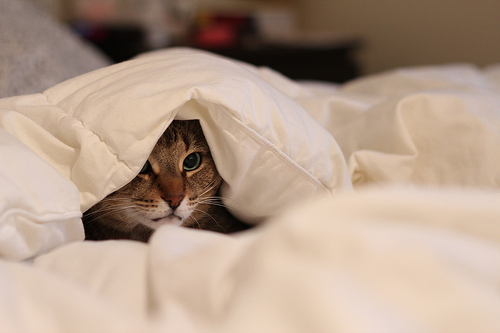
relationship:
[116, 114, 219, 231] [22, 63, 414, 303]
cat under the covers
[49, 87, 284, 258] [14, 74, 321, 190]
cat under covers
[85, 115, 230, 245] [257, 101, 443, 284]
cat hiding under blanket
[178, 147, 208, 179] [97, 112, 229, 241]
eye of cat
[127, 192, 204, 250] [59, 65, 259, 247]
mouth of cat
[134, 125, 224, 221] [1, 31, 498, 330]
cat under blanket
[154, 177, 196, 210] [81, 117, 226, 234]
nose on a cat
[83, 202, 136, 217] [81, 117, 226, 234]
whisker on a cat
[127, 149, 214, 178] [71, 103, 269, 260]
cat eyes of cat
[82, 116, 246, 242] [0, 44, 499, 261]
cat`s head poking out of blanket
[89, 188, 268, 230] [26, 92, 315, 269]
whiskers of cat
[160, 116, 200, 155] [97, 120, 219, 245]
stripes on head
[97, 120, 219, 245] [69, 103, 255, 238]
head of cat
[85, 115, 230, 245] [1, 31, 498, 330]
cat under blanket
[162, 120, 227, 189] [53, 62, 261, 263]
eye of cat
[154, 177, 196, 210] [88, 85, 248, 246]
nose of cat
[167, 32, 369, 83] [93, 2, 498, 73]
desk in background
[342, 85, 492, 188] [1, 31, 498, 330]
wrinkle in blanket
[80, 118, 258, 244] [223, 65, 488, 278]
cat in sheets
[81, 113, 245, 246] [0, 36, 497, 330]
cat under covers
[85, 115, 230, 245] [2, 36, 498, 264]
cat under covers